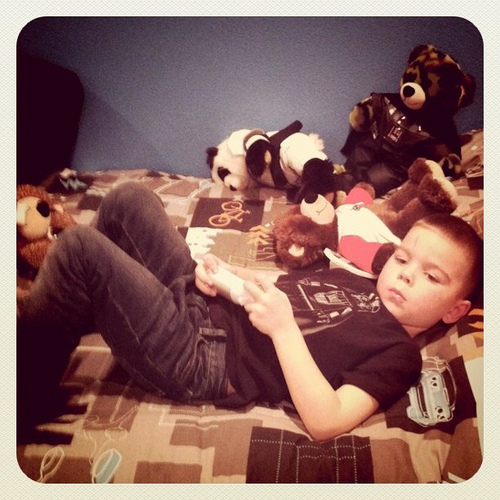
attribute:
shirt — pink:
[333, 186, 401, 271]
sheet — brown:
[19, 167, 483, 484]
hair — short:
[401, 214, 485, 268]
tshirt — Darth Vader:
[216, 257, 389, 445]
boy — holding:
[46, 180, 451, 421]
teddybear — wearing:
[262, 120, 302, 175]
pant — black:
[17, 182, 223, 402]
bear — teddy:
[337, 40, 472, 173]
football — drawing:
[43, 164, 98, 196]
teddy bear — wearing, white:
[273, 156, 463, 276]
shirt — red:
[324, 187, 408, 277]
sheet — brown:
[30, 167, 479, 369]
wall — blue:
[85, 45, 348, 115]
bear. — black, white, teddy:
[303, 32, 493, 228]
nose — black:
[402, 85, 414, 97]